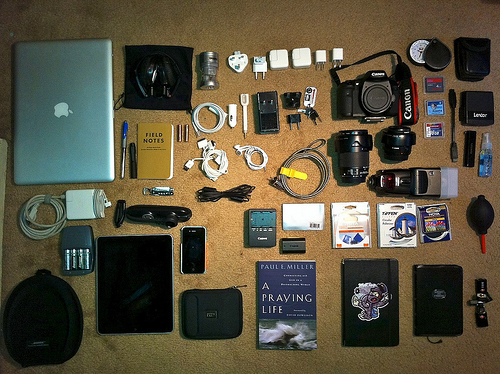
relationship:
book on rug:
[255, 257, 315, 349] [8, 20, 495, 370]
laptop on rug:
[10, 36, 115, 185] [8, 20, 495, 370]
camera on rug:
[337, 69, 397, 125] [8, 20, 495, 370]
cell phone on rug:
[178, 223, 207, 277] [8, 20, 495, 370]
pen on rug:
[114, 119, 128, 170] [118, 7, 443, 37]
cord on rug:
[265, 136, 337, 201] [8, 20, 495, 370]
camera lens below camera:
[332, 126, 377, 183] [332, 52, 417, 122]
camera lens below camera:
[380, 126, 417, 162] [332, 52, 417, 122]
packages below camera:
[323, 204, 453, 254] [328, 51, 419, 131]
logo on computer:
[53, 100, 73, 118] [10, 37, 115, 188]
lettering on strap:
[394, 82, 418, 130] [324, 49, 405, 82]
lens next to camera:
[329, 119, 375, 188] [327, 45, 422, 131]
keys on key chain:
[302, 104, 319, 122] [294, 75, 328, 127]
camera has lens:
[337, 67, 418, 124] [337, 129, 373, 181]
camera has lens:
[337, 67, 418, 124] [381, 125, 416, 160]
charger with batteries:
[54, 224, 100, 282] [65, 247, 91, 271]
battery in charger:
[64, 249, 73, 271] [54, 224, 100, 282]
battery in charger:
[67, 247, 77, 270] [54, 224, 100, 282]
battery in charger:
[76, 248, 86, 270] [54, 224, 100, 282]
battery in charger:
[82, 247, 92, 271] [54, 224, 100, 282]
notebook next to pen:
[134, 119, 175, 183] [118, 121, 128, 179]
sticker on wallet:
[352, 281, 393, 320] [341, 256, 401, 346]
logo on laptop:
[54, 102, 74, 118] [10, 36, 115, 185]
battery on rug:
[62, 248, 74, 272] [145, 342, 176, 364]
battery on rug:
[70, 249, 78, 270] [145, 342, 176, 364]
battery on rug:
[77, 249, 86, 270] [145, 342, 176, 364]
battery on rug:
[84, 248, 91, 269] [145, 342, 176, 364]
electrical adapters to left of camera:
[224, 43, 350, 70] [338, 76, 407, 119]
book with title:
[255, 257, 318, 351] [252, 280, 315, 320]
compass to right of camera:
[388, 30, 458, 75] [319, 43, 434, 133]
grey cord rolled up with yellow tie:
[270, 141, 330, 202] [276, 159, 309, 183]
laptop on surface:
[10, 36, 112, 195] [20, 13, 478, 366]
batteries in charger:
[59, 244, 97, 274] [60, 205, 106, 280]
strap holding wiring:
[273, 160, 316, 189] [262, 153, 316, 197]